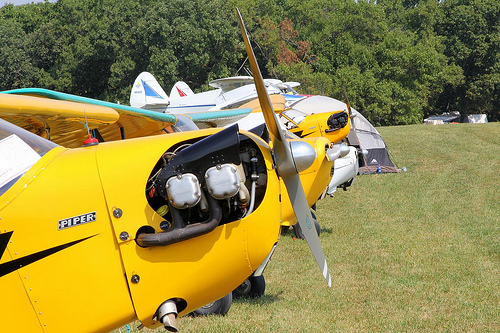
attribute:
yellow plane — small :
[10, 87, 328, 306]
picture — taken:
[0, 2, 496, 330]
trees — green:
[2, 0, 499, 125]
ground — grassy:
[394, 148, 436, 182]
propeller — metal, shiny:
[202, 0, 354, 292]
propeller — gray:
[217, 0, 381, 300]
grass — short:
[168, 119, 497, 331]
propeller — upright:
[38, 43, 415, 249]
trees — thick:
[357, 1, 496, 106]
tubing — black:
[135, 202, 227, 247]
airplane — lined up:
[2, 2, 339, 332]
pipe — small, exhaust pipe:
[160, 313, 179, 330]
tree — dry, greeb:
[251, 10, 397, 67]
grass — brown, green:
[382, 188, 492, 300]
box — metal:
[163, 169, 201, 206]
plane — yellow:
[5, 6, 336, 330]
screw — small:
[123, 271, 144, 282]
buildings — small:
[413, 106, 493, 121]